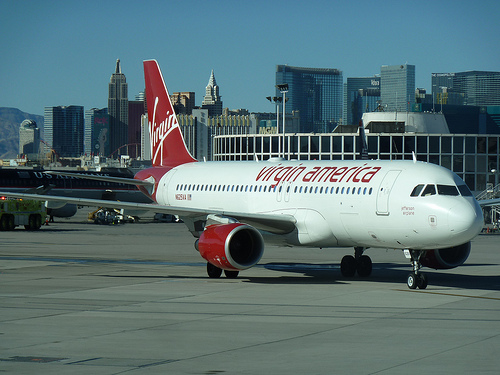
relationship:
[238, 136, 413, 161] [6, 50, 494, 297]
windows on plane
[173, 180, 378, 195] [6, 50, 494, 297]
windows on side plane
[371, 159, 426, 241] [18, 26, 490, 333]
door on plane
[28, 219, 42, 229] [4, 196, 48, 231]
tire on truck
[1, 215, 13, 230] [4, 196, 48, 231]
tire on truck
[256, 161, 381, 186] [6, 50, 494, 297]
company name of plane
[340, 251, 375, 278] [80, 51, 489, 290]
landing gear of plane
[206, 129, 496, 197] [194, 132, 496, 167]
building with walls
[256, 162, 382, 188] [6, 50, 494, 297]
company name on plane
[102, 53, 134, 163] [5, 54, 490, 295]
building behind park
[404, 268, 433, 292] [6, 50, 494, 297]
wheel in front of plane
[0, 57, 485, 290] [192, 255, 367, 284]
airplane has landing gear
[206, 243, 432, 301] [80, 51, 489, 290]
landing gear down on plane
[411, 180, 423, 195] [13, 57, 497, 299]
window on front airplane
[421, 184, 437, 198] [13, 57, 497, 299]
window on front airplane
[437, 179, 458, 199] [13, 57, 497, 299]
window on front airplane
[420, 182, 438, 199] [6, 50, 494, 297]
window in front plane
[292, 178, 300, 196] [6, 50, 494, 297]
window on side plane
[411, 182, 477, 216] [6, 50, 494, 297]
cockpit of plane